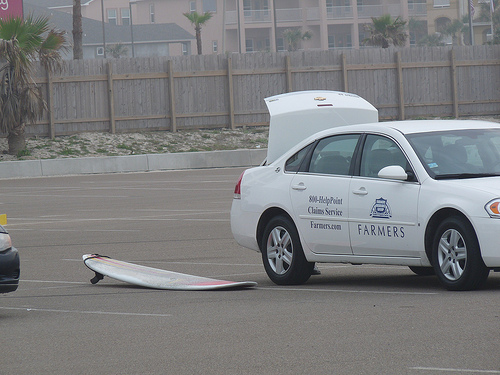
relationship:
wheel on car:
[222, 204, 343, 296] [200, 55, 486, 307]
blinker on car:
[223, 165, 264, 216] [200, 55, 486, 307]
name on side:
[352, 207, 417, 242] [259, 162, 471, 275]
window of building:
[236, 8, 276, 30] [49, 10, 373, 135]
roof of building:
[97, 5, 170, 45] [49, 10, 373, 135]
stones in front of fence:
[22, 121, 264, 150] [12, 36, 281, 167]